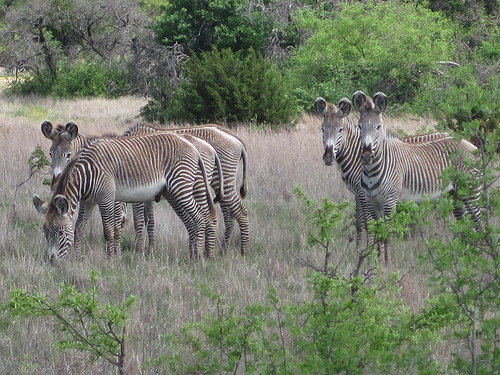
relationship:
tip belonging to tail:
[239, 183, 248, 199] [239, 182, 248, 199]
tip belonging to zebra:
[239, 183, 248, 199] [114, 113, 251, 255]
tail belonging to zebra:
[239, 182, 248, 199] [114, 113, 251, 255]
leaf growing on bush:
[304, 280, 312, 285] [283, 185, 440, 373]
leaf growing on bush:
[330, 283, 334, 287] [283, 185, 440, 373]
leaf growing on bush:
[369, 316, 374, 321] [283, 185, 440, 373]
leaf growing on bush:
[330, 346, 335, 350] [283, 185, 440, 373]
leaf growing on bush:
[366, 220, 372, 225] [283, 185, 440, 373]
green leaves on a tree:
[187, 4, 234, 40] [141, 0, 274, 61]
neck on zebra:
[358, 137, 388, 185] [348, 90, 487, 232]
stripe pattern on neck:
[358, 159, 388, 190] [358, 137, 388, 185]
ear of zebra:
[55, 195, 68, 214] [33, 130, 217, 265]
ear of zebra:
[28, 191, 51, 209] [33, 130, 217, 265]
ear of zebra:
[376, 88, 391, 116] [348, 90, 487, 232]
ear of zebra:
[352, 84, 369, 108] [348, 90, 487, 232]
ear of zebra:
[51, 193, 69, 215] [308, 90, 462, 228]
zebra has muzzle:
[315, 97, 450, 264] [314, 101, 356, 167]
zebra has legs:
[33, 130, 217, 265] [169, 187, 206, 257]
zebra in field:
[349, 90, 486, 265] [0, 76, 499, 374]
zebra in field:
[315, 97, 450, 264] [0, 76, 499, 374]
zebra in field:
[33, 130, 217, 265] [0, 76, 499, 374]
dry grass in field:
[0, 68, 499, 374] [0, 76, 499, 374]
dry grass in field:
[256, 204, 308, 282] [11, 62, 484, 319]